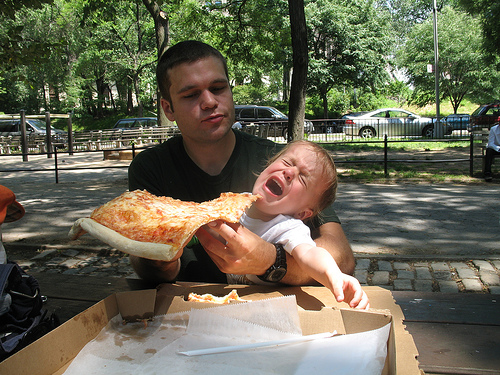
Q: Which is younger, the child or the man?
A: The child is younger than the man.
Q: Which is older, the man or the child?
A: The man is older than the child.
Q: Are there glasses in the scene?
A: No, there are no glasses.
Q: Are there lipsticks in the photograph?
A: No, there are no lipsticks.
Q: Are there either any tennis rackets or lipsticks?
A: No, there are no lipsticks or tennis rackets.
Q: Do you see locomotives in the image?
A: No, there are no locomotives.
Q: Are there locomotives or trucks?
A: No, there are no locomotives or trucks.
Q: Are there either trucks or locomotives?
A: No, there are no locomotives or trucks.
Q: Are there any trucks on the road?
A: No, there is a car on the road.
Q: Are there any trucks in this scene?
A: No, there are no trucks.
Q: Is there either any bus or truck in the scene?
A: No, there are no trucks or buses.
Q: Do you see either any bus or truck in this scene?
A: No, there are no trucks or buses.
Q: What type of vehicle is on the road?
A: The vehicle is a car.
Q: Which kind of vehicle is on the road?
A: The vehicle is a car.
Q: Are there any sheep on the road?
A: No, there is a car on the road.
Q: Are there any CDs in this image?
A: No, there are no cds.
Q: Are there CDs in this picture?
A: No, there are no cds.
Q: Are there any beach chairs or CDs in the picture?
A: No, there are no CDs or beach chairs.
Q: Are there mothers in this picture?
A: No, there are no mothers.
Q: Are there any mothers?
A: No, there are no mothers.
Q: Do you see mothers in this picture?
A: No, there are no mothers.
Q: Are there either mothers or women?
A: No, there are no mothers or women.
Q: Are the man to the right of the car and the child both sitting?
A: Yes, both the man and the child are sitting.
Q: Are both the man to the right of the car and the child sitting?
A: Yes, both the man and the child are sitting.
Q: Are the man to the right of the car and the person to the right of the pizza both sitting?
A: Yes, both the man and the child are sitting.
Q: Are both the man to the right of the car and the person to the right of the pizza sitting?
A: Yes, both the man and the child are sitting.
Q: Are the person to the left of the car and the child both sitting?
A: Yes, both the man and the child are sitting.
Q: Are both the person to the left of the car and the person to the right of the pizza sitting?
A: Yes, both the man and the child are sitting.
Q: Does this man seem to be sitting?
A: Yes, the man is sitting.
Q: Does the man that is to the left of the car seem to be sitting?
A: Yes, the man is sitting.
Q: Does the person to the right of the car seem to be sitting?
A: Yes, the man is sitting.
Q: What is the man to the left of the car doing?
A: The man is sitting.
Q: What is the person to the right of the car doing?
A: The man is sitting.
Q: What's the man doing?
A: The man is sitting.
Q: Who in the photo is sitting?
A: The man is sitting.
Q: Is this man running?
A: No, the man is sitting.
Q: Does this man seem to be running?
A: No, the man is sitting.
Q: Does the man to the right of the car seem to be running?
A: No, the man is sitting.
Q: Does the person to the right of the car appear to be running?
A: No, the man is sitting.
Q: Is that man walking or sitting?
A: The man is sitting.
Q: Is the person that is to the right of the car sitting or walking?
A: The man is sitting.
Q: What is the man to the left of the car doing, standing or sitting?
A: The man is sitting.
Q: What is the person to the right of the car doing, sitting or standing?
A: The man is sitting.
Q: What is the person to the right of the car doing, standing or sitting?
A: The man is sitting.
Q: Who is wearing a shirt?
A: The man is wearing a shirt.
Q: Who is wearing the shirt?
A: The man is wearing a shirt.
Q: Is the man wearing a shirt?
A: Yes, the man is wearing a shirt.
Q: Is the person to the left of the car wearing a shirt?
A: Yes, the man is wearing a shirt.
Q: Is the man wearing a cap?
A: No, the man is wearing a shirt.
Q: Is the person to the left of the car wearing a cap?
A: No, the man is wearing a shirt.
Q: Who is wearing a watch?
A: The man is wearing a watch.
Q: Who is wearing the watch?
A: The man is wearing a watch.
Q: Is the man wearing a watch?
A: Yes, the man is wearing a watch.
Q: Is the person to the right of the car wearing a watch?
A: Yes, the man is wearing a watch.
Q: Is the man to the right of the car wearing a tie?
A: No, the man is wearing a watch.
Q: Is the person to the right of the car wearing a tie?
A: No, the man is wearing a watch.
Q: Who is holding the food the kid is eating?
A: The man is holding the pizza.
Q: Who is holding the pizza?
A: The man is holding the pizza.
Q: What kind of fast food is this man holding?
A: The man is holding the pizza.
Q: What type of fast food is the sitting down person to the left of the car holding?
A: The man is holding the pizza.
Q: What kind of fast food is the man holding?
A: The man is holding the pizza.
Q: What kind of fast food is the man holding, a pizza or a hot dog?
A: The man is holding a pizza.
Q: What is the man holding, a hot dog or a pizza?
A: The man is holding a pizza.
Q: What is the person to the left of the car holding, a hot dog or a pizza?
A: The man is holding a pizza.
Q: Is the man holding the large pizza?
A: Yes, the man is holding the pizza.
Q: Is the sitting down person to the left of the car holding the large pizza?
A: Yes, the man is holding the pizza.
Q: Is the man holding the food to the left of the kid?
A: Yes, the man is holding the pizza.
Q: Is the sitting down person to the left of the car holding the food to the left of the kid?
A: Yes, the man is holding the pizza.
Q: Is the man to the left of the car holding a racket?
A: No, the man is holding the pizza.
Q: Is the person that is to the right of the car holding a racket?
A: No, the man is holding the pizza.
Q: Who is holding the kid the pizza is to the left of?
A: The man is holding the kid.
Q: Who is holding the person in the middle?
A: The man is holding the kid.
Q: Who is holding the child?
A: The man is holding the kid.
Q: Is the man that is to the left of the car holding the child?
A: Yes, the man is holding the child.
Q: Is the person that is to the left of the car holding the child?
A: Yes, the man is holding the child.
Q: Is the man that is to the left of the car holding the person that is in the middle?
A: Yes, the man is holding the child.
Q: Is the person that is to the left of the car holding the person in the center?
A: Yes, the man is holding the child.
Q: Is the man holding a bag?
A: No, the man is holding the child.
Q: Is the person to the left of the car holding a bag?
A: No, the man is holding the child.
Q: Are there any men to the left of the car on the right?
A: Yes, there is a man to the left of the car.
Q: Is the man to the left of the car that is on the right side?
A: Yes, the man is to the left of the car.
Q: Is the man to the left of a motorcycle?
A: No, the man is to the left of the car.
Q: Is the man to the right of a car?
A: No, the man is to the left of a car.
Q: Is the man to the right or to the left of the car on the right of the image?
A: The man is to the left of the car.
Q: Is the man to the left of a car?
A: No, the man is to the right of a car.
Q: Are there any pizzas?
A: Yes, there is a pizza.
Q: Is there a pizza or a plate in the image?
A: Yes, there is a pizza.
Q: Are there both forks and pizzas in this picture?
A: No, there is a pizza but no forks.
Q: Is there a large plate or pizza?
A: Yes, there is a large pizza.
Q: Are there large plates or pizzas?
A: Yes, there is a large pizza.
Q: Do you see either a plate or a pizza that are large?
A: Yes, the pizza is large.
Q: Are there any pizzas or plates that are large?
A: Yes, the pizza is large.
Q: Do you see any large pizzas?
A: Yes, there is a large pizza.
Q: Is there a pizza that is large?
A: Yes, there is a pizza that is large.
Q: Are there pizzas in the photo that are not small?
A: Yes, there is a large pizza.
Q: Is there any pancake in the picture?
A: No, there are no pancakes.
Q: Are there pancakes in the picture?
A: No, there are no pancakes.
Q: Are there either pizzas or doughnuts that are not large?
A: No, there is a pizza but it is large.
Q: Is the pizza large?
A: Yes, the pizza is large.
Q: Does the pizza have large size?
A: Yes, the pizza is large.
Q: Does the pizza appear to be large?
A: Yes, the pizza is large.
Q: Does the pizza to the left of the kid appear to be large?
A: Yes, the pizza is large.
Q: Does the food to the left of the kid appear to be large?
A: Yes, the pizza is large.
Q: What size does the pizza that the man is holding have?
A: The pizza has large size.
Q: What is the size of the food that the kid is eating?
A: The pizza is large.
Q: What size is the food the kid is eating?
A: The pizza is large.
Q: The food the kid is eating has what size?
A: The pizza is large.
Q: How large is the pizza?
A: The pizza is large.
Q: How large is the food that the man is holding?
A: The pizza is large.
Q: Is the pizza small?
A: No, the pizza is large.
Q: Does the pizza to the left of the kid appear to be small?
A: No, the pizza is large.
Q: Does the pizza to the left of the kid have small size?
A: No, the pizza is large.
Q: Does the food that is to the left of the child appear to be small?
A: No, the pizza is large.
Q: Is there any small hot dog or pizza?
A: No, there is a pizza but it is large.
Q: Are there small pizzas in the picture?
A: No, there is a pizza but it is large.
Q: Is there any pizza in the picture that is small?
A: No, there is a pizza but it is large.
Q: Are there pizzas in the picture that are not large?
A: No, there is a pizza but it is large.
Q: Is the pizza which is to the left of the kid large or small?
A: The pizza is large.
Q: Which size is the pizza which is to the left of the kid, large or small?
A: The pizza is large.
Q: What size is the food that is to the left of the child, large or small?
A: The pizza is large.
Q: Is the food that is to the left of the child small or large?
A: The pizza is large.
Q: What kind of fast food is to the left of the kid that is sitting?
A: The food is a pizza.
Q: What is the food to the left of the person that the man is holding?
A: The food is a pizza.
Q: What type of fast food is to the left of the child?
A: The food is a pizza.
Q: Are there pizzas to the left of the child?
A: Yes, there is a pizza to the left of the child.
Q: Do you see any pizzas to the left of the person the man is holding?
A: Yes, there is a pizza to the left of the child.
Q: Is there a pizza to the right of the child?
A: No, the pizza is to the left of the child.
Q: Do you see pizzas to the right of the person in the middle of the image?
A: No, the pizza is to the left of the child.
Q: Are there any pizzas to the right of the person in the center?
A: No, the pizza is to the left of the child.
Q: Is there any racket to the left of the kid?
A: No, there is a pizza to the left of the kid.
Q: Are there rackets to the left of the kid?
A: No, there is a pizza to the left of the kid.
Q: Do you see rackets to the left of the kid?
A: No, there is a pizza to the left of the kid.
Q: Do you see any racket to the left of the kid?
A: No, there is a pizza to the left of the kid.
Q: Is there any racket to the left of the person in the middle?
A: No, there is a pizza to the left of the kid.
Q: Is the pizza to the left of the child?
A: Yes, the pizza is to the left of the child.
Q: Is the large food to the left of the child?
A: Yes, the pizza is to the left of the child.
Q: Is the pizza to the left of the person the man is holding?
A: Yes, the pizza is to the left of the child.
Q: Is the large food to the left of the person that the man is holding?
A: Yes, the pizza is to the left of the child.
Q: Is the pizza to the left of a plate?
A: No, the pizza is to the left of the child.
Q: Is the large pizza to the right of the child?
A: No, the pizza is to the left of the child.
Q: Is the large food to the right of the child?
A: No, the pizza is to the left of the child.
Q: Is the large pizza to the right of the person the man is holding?
A: No, the pizza is to the left of the child.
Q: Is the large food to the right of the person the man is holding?
A: No, the pizza is to the left of the child.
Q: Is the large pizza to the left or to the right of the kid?
A: The pizza is to the left of the kid.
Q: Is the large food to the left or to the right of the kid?
A: The pizza is to the left of the kid.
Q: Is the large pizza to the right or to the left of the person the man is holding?
A: The pizza is to the left of the kid.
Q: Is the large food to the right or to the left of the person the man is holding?
A: The pizza is to the left of the kid.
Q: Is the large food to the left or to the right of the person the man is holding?
A: The pizza is to the left of the kid.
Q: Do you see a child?
A: Yes, there is a child.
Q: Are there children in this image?
A: Yes, there is a child.